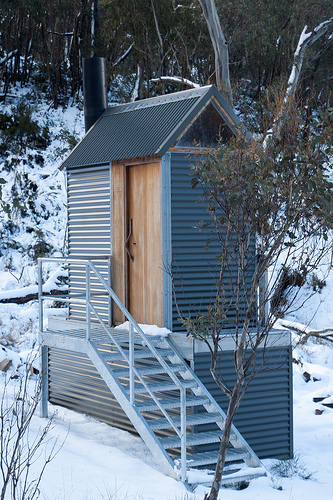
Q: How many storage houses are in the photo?
A: One.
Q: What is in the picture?
A: Storage house.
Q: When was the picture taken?
A: Daytime.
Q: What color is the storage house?
A: Blue.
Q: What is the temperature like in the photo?
A: Cold.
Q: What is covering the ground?
A: Snow.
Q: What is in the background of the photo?
A: Trees.